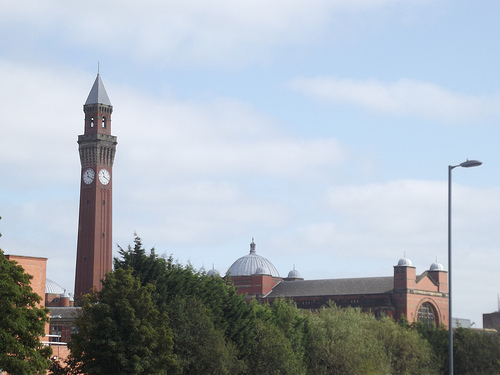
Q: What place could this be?
A: It is a church.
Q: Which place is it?
A: It is a church.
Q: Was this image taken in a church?
A: Yes, it was taken in a church.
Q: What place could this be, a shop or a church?
A: It is a church.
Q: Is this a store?
A: No, it is a church.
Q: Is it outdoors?
A: Yes, it is outdoors.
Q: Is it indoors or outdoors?
A: It is outdoors.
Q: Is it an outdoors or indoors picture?
A: It is outdoors.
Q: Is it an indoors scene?
A: No, it is outdoors.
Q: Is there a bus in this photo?
A: No, there are no buses.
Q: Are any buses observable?
A: No, there are no buses.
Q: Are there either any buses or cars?
A: No, there are no buses or cars.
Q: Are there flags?
A: No, there are no flags.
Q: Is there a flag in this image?
A: No, there are no flags.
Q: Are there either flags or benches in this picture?
A: No, there are no flags or benches.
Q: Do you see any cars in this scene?
A: No, there are no cars.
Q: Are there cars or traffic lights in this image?
A: No, there are no cars or traffic lights.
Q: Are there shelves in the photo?
A: No, there are no shelves.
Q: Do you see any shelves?
A: No, there are no shelves.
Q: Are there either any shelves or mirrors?
A: No, there are no shelves or mirrors.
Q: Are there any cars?
A: No, there are no cars.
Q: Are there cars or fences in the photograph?
A: No, there are no cars or fences.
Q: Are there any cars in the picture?
A: No, there are no cars.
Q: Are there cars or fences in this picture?
A: No, there are no cars or fences.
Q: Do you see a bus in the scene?
A: No, there are no buses.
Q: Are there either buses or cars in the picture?
A: No, there are no buses or cars.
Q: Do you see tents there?
A: No, there are no tents.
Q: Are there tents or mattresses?
A: No, there are no tents or mattresses.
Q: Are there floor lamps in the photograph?
A: No, there are no floor lamps.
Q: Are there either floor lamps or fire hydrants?
A: No, there are no floor lamps or fire hydrants.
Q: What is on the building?
A: The dome is on the building.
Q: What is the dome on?
A: The dome is on the building.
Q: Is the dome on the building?
A: Yes, the dome is on the building.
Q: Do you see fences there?
A: No, there are no fences.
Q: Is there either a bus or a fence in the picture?
A: No, there are no fences or buses.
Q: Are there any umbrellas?
A: No, there are no umbrellas.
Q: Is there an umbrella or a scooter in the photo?
A: No, there are no umbrellas or scooters.